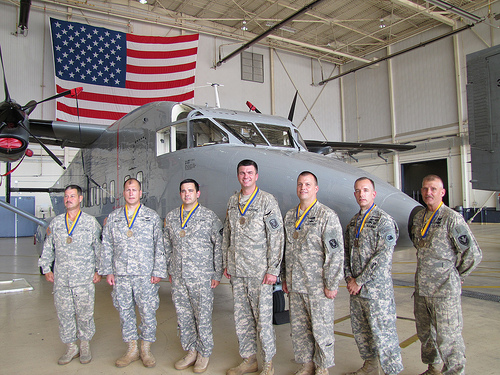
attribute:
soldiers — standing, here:
[54, 149, 409, 304]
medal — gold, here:
[152, 179, 200, 223]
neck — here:
[174, 201, 210, 218]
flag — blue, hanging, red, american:
[59, 19, 208, 133]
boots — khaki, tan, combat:
[117, 332, 168, 374]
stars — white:
[62, 3, 114, 64]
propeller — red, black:
[13, 114, 61, 184]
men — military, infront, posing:
[68, 188, 479, 341]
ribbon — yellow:
[117, 198, 135, 213]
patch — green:
[249, 212, 287, 233]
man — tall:
[209, 129, 306, 335]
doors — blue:
[9, 193, 66, 243]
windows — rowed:
[68, 165, 152, 232]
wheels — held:
[251, 285, 293, 315]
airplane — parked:
[104, 114, 491, 273]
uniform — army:
[221, 207, 282, 276]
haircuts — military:
[54, 172, 221, 195]